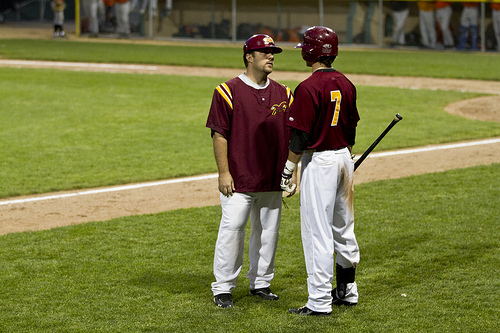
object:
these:
[180, 42, 381, 333]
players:
[203, 33, 297, 308]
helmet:
[294, 25, 338, 63]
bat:
[352, 113, 403, 171]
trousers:
[299, 146, 360, 313]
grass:
[105, 50, 139, 59]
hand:
[218, 174, 236, 198]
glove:
[280, 159, 299, 193]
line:
[447, 141, 481, 149]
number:
[330, 90, 342, 127]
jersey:
[205, 71, 294, 193]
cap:
[242, 34, 283, 55]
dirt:
[415, 80, 421, 84]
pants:
[211, 190, 283, 296]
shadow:
[416, 265, 450, 276]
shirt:
[287, 71, 361, 152]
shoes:
[249, 287, 279, 300]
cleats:
[335, 263, 355, 299]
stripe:
[215, 82, 233, 110]